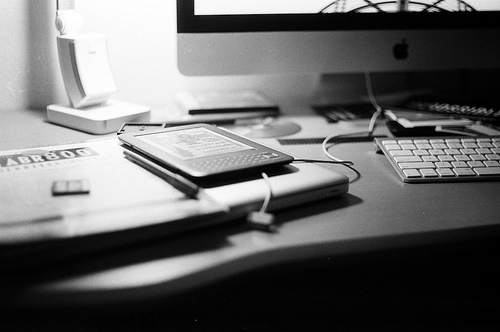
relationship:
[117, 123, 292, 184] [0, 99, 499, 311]
e-reader on top of table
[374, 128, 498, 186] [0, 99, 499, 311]
electronic on top of table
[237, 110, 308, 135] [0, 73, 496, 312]
cd laying on desk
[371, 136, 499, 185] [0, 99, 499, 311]
keyboard on top of table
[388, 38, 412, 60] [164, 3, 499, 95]
apple symbol on computer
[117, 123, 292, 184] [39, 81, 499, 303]
e-reader on top of desk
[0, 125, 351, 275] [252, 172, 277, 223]
laptop under charger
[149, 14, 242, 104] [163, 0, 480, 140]
white part of computer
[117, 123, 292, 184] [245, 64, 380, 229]
e-reader on top of charger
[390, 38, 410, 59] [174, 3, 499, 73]
apple symbol on computer monitor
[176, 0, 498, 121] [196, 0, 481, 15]
computer has screen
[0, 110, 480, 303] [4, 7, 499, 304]
desk top has gadgets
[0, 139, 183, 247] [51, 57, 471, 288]
magazine sitting on desk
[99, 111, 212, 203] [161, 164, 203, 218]
pen has pen cap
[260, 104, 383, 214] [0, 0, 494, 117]
cord goes to wall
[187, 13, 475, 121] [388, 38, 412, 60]
monitor has apple symbol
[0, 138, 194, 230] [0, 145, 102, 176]
material has writing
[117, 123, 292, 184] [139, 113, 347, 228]
e-reader has screen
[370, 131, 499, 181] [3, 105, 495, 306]
keyboard on table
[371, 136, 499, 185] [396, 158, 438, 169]
keyboard has number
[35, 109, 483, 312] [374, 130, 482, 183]
table under keyboard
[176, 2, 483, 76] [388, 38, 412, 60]
computer has apple symbol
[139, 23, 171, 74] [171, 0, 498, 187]
light behind computer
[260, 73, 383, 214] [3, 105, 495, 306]
cord on table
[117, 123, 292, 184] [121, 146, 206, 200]
e-reader has pen